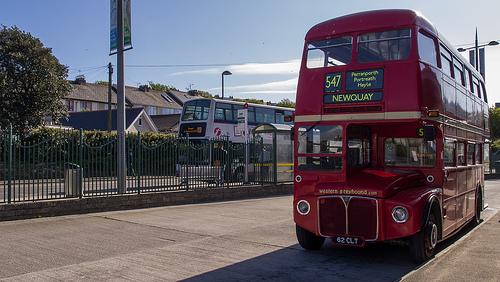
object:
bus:
[293, 9, 491, 252]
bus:
[174, 98, 294, 183]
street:
[0, 171, 499, 281]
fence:
[0, 122, 274, 203]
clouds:
[171, 59, 299, 95]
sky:
[148, 7, 258, 52]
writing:
[323, 68, 379, 102]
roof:
[44, 79, 207, 138]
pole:
[117, 0, 127, 193]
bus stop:
[247, 123, 294, 183]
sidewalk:
[402, 211, 499, 281]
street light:
[221, 70, 230, 98]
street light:
[454, 27, 497, 65]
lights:
[232, 199, 279, 218]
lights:
[155, 214, 217, 239]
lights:
[119, 209, 148, 229]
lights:
[45, 218, 90, 243]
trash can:
[64, 162, 84, 197]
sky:
[211, 0, 254, 66]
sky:
[255, 4, 300, 102]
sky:
[1, 1, 103, 75]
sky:
[432, 3, 494, 49]